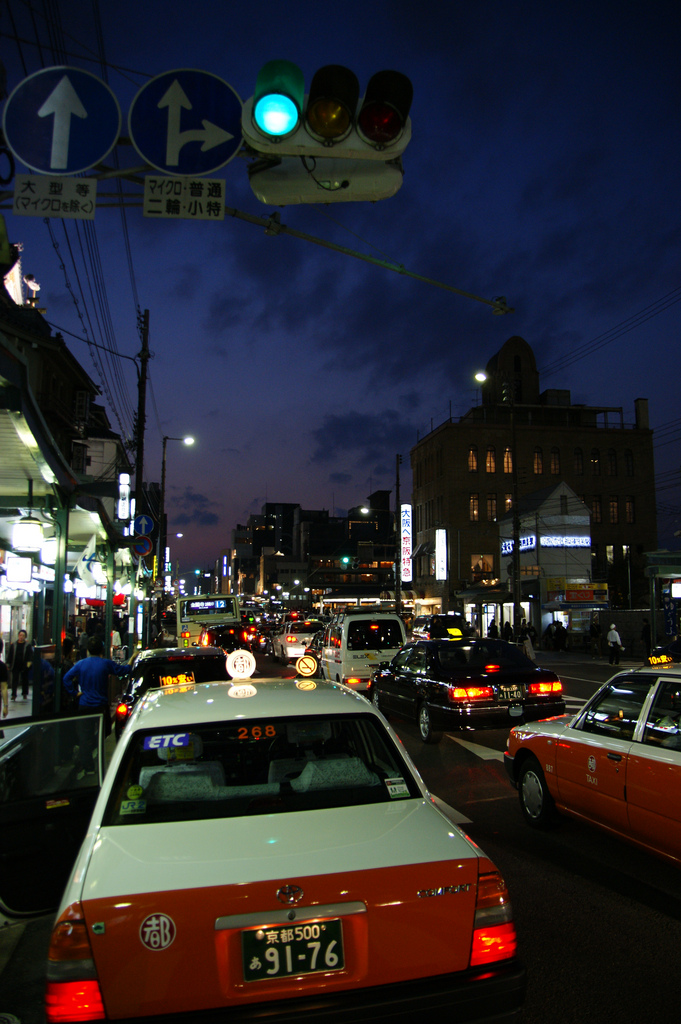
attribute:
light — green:
[252, 91, 300, 140]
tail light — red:
[467, 920, 516, 969]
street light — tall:
[158, 431, 194, 589]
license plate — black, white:
[238, 915, 346, 985]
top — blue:
[65, 652, 124, 705]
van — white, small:
[317, 612, 405, 690]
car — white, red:
[0, 648, 515, 1021]